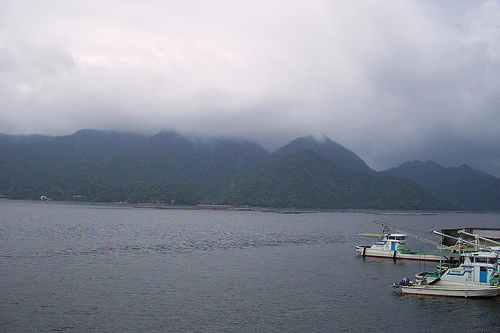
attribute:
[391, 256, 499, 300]
boat — blue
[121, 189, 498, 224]
landings — brown 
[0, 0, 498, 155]
sky. — cloudy, foggy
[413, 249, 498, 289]
boat — white 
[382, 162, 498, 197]
hill — small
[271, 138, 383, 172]
mountain — tallest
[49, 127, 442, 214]
hills — many, tree covered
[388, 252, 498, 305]
boat — small 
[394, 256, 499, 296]
boat — large 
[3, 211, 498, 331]
water — large , far edge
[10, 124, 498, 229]
tree — green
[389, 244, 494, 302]
boat — large 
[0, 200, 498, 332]
sea — gray 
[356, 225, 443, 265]
boat — longest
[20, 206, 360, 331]
water — large 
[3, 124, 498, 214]
mountain — large 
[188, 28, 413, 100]
sky — grey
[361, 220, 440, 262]
boat — white 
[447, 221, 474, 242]
structure — brown 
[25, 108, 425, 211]
hill — small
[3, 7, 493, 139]
foggysky — white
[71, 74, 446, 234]
hill — small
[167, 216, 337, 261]
ripples — line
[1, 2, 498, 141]
sky — foggy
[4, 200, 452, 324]
surface — water